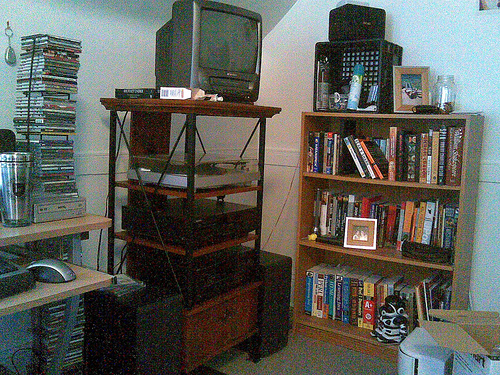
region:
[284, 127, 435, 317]
plenty books on shelf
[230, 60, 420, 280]
plenty books on shelf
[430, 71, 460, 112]
a jar with values .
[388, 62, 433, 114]
a brown frame and a picture.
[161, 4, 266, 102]
a television set.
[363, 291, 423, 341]
a black and white toy robot.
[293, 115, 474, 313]
a book shelf full of books.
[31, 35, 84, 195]
a stack of cds.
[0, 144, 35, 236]
a silver and black drinking cup.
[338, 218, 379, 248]
a picture of a man and woman.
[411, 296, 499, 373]
a white cardboard box.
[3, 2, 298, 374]
a entertainment center.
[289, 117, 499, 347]
books on a bookcase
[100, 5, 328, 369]
a TV on a shelf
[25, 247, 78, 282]
a mouse on the desk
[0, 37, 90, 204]
cds on the desk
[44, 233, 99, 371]
cds under the desk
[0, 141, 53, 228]
a coffee cup on the desk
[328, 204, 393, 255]
a picture frame on the bookcase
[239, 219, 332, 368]
a computer on the ground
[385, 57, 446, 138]
a picture frame on top of the bookcase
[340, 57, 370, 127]
air freshener in a container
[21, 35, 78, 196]
tall pile of CDs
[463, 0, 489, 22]
small window in wall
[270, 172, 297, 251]
electrical cord against wall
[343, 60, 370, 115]
blue aerosol can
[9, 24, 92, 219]
stack of books on table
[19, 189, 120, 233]
large silver dvd player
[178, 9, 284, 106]
old fashioned gray television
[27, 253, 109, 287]
silver mouse on table top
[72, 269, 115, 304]
edge of desk top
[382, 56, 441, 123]
tan silver frame with picture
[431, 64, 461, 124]
clear round jar on surface